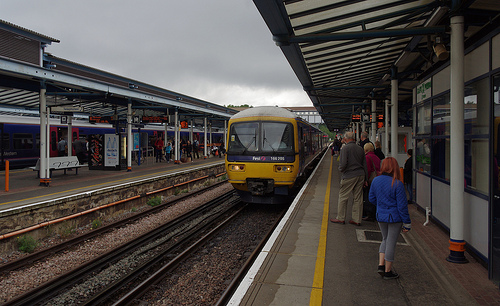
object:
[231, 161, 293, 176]
lights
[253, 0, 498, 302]
building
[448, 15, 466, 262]
white pole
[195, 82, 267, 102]
cloud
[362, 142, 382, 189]
woman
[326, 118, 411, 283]
people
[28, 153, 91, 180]
bench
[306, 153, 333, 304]
line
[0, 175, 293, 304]
tracks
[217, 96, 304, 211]
train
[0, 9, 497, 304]
station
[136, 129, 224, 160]
people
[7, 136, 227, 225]
platform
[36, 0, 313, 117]
sky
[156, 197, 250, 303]
train tracks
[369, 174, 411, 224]
coat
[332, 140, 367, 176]
sweater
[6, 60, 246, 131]
awning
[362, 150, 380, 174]
jacket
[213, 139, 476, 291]
platform